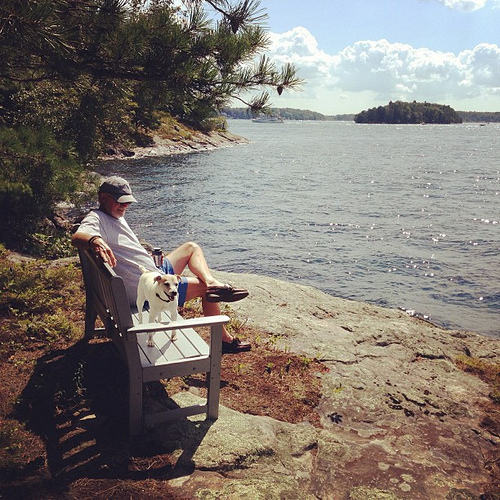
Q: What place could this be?
A: It is a lake.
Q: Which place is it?
A: It is a lake.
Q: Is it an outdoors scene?
A: Yes, it is outdoors.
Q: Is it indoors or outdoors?
A: It is outdoors.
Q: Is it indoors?
A: No, it is outdoors.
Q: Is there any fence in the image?
A: No, there are no fences.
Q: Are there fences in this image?
A: No, there are no fences.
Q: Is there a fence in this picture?
A: No, there are no fences.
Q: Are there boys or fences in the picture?
A: No, there are no fences or boys.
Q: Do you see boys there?
A: No, there are no boys.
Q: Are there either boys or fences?
A: No, there are no boys or fences.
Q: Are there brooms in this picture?
A: No, there are no brooms.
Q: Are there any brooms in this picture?
A: No, there are no brooms.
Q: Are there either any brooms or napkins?
A: No, there are no brooms or napkins.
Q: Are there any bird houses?
A: No, there are no bird houses.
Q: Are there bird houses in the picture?
A: No, there are no bird houses.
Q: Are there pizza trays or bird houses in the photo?
A: No, there are no bird houses or pizza trays.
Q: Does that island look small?
A: Yes, the island is small.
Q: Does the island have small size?
A: Yes, the island is small.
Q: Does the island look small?
A: Yes, the island is small.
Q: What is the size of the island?
A: The island is small.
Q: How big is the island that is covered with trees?
A: The island is small.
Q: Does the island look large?
A: No, the island is small.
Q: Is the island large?
A: No, the island is small.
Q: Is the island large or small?
A: The island is small.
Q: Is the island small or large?
A: The island is small.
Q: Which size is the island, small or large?
A: The island is small.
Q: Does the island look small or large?
A: The island is small.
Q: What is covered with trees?
A: The island is covered with trees.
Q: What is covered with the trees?
A: The island is covered with trees.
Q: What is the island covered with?
A: The island is covered with trees.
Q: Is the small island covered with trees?
A: Yes, the island is covered with trees.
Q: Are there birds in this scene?
A: No, there are no birds.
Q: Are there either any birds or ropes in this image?
A: No, there are no birds or ropes.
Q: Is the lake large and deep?
A: Yes, the lake is large and deep.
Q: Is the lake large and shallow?
A: No, the lake is large but deep.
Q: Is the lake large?
A: Yes, the lake is large.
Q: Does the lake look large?
A: Yes, the lake is large.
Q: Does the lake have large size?
A: Yes, the lake is large.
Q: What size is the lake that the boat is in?
A: The lake is large.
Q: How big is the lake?
A: The lake is large.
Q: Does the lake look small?
A: No, the lake is large.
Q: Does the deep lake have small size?
A: No, the lake is large.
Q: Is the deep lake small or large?
A: The lake is large.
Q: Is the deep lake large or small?
A: The lake is large.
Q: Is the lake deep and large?
A: Yes, the lake is deep and large.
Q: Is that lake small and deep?
A: No, the lake is deep but large.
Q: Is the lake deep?
A: Yes, the lake is deep.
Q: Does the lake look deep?
A: Yes, the lake is deep.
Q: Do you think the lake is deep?
A: Yes, the lake is deep.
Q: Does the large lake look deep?
A: Yes, the lake is deep.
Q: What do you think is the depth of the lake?
A: The lake is deep.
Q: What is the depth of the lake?
A: The lake is deep.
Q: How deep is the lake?
A: The lake is deep.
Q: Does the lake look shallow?
A: No, the lake is deep.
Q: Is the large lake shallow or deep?
A: The lake is deep.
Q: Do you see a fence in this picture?
A: No, there are no fences.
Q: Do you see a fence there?
A: No, there are no fences.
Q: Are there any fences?
A: No, there are no fences.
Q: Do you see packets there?
A: No, there are no packets.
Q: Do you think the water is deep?
A: Yes, the water is deep.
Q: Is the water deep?
A: Yes, the water is deep.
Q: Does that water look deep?
A: Yes, the water is deep.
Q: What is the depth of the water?
A: The water is deep.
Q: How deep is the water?
A: The water is deep.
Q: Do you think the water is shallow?
A: No, the water is deep.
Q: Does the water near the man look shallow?
A: No, the water is deep.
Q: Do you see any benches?
A: Yes, there is a bench.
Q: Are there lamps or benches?
A: Yes, there is a bench.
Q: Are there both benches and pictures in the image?
A: No, there is a bench but no pictures.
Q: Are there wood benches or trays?
A: Yes, there is a wood bench.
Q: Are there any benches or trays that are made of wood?
A: Yes, the bench is made of wood.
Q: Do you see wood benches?
A: Yes, there is a wood bench.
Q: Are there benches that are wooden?
A: Yes, there is a bench that is wooden.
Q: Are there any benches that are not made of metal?
A: Yes, there is a bench that is made of wood.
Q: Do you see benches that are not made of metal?
A: Yes, there is a bench that is made of wood.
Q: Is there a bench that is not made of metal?
A: Yes, there is a bench that is made of wood.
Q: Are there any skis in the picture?
A: No, there are no skis.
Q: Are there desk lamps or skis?
A: No, there are no skis or desk lamps.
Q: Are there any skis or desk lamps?
A: No, there are no skis or desk lamps.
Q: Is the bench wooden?
A: Yes, the bench is wooden.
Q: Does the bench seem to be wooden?
A: Yes, the bench is wooden.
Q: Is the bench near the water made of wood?
A: Yes, the bench is made of wood.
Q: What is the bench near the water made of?
A: The bench is made of wood.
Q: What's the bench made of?
A: The bench is made of wood.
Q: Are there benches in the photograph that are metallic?
A: No, there is a bench but it is wooden.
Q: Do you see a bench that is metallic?
A: No, there is a bench but it is wooden.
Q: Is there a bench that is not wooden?
A: No, there is a bench but it is wooden.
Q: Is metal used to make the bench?
A: No, the bench is made of wood.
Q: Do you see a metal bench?
A: No, there is a bench but it is made of wood.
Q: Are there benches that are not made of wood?
A: No, there is a bench but it is made of wood.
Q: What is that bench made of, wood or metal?
A: The bench is made of wood.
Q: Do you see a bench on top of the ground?
A: Yes, there is a bench on top of the ground.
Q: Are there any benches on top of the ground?
A: Yes, there is a bench on top of the ground.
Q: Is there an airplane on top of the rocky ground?
A: No, there is a bench on top of the ground.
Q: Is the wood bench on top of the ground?
A: Yes, the bench is on top of the ground.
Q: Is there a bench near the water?
A: Yes, there is a bench near the water.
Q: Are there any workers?
A: No, there are no workers.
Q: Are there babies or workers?
A: No, there are no workers or babies.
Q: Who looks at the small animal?
A: The man looks at the dog.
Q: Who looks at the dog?
A: The man looks at the dog.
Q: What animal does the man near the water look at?
A: The man looks at the dog.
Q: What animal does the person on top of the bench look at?
A: The man looks at the dog.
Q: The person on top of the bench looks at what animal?
A: The man looks at the dog.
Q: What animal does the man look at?
A: The man looks at the dog.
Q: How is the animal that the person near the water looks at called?
A: The animal is a dog.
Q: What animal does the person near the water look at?
A: The man looks at the dog.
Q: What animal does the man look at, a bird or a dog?
A: The man looks at a dog.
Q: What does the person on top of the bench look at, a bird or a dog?
A: The man looks at a dog.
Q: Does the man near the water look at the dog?
A: Yes, the man looks at the dog.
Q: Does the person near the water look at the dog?
A: Yes, the man looks at the dog.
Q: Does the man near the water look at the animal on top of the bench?
A: Yes, the man looks at the dog.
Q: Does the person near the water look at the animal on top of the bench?
A: Yes, the man looks at the dog.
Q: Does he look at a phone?
A: No, the man looks at the dog.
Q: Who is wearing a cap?
A: The man is wearing a cap.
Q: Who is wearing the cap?
A: The man is wearing a cap.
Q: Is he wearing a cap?
A: Yes, the man is wearing a cap.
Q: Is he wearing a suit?
A: No, the man is wearing a cap.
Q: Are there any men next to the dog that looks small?
A: Yes, there is a man next to the dog.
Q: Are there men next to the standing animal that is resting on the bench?
A: Yes, there is a man next to the dog.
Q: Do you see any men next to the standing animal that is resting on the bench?
A: Yes, there is a man next to the dog.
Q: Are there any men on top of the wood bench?
A: Yes, there is a man on top of the bench.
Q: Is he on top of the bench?
A: Yes, the man is on top of the bench.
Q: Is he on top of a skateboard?
A: No, the man is on top of the bench.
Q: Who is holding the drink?
A: The man is holding the drink.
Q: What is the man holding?
A: The man is holding the drink.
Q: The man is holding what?
A: The man is holding the drink.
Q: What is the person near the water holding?
A: The man is holding the drink.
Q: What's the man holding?
A: The man is holding the drink.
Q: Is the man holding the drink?
A: Yes, the man is holding the drink.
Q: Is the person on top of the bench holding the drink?
A: Yes, the man is holding the drink.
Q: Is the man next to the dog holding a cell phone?
A: No, the man is holding the drink.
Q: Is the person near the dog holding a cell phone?
A: No, the man is holding the drink.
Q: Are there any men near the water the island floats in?
A: Yes, there is a man near the water.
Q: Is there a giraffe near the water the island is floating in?
A: No, there is a man near the water.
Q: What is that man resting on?
A: The man is resting on the bench.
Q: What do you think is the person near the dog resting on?
A: The man is resting on the bench.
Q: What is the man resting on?
A: The man is resting on the bench.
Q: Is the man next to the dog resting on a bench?
A: Yes, the man is resting on a bench.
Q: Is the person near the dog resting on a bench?
A: Yes, the man is resting on a bench.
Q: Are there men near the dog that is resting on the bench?
A: Yes, there is a man near the dog.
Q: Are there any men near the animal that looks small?
A: Yes, there is a man near the dog.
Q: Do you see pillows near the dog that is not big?
A: No, there is a man near the dog.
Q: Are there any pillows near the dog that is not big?
A: No, there is a man near the dog.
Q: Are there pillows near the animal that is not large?
A: No, there is a man near the dog.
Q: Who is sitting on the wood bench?
A: The man is sitting on the bench.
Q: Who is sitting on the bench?
A: The man is sitting on the bench.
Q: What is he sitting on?
A: The man is sitting on the bench.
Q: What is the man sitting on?
A: The man is sitting on the bench.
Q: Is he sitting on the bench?
A: Yes, the man is sitting on the bench.